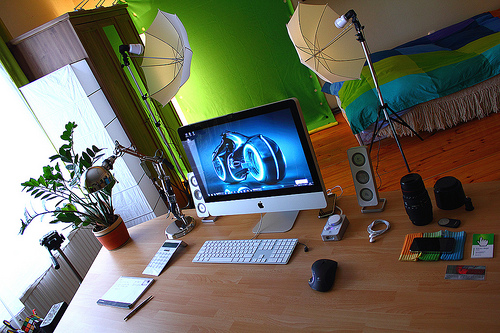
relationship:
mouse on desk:
[302, 254, 338, 296] [41, 177, 499, 332]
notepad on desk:
[93, 269, 158, 310] [41, 177, 499, 332]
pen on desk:
[123, 292, 156, 323] [41, 177, 499, 332]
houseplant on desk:
[11, 119, 137, 259] [41, 177, 499, 332]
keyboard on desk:
[187, 233, 301, 268] [41, 177, 499, 332]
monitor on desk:
[172, 90, 334, 237] [41, 177, 499, 332]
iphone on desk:
[408, 234, 458, 256] [41, 177, 499, 332]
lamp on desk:
[76, 133, 197, 241] [41, 177, 499, 332]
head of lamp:
[75, 162, 117, 195] [76, 133, 197, 241]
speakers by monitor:
[343, 141, 389, 218] [172, 90, 334, 237]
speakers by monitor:
[185, 169, 222, 226] [172, 90, 334, 237]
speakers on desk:
[343, 141, 389, 218] [41, 177, 499, 332]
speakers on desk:
[185, 169, 222, 226] [41, 177, 499, 332]